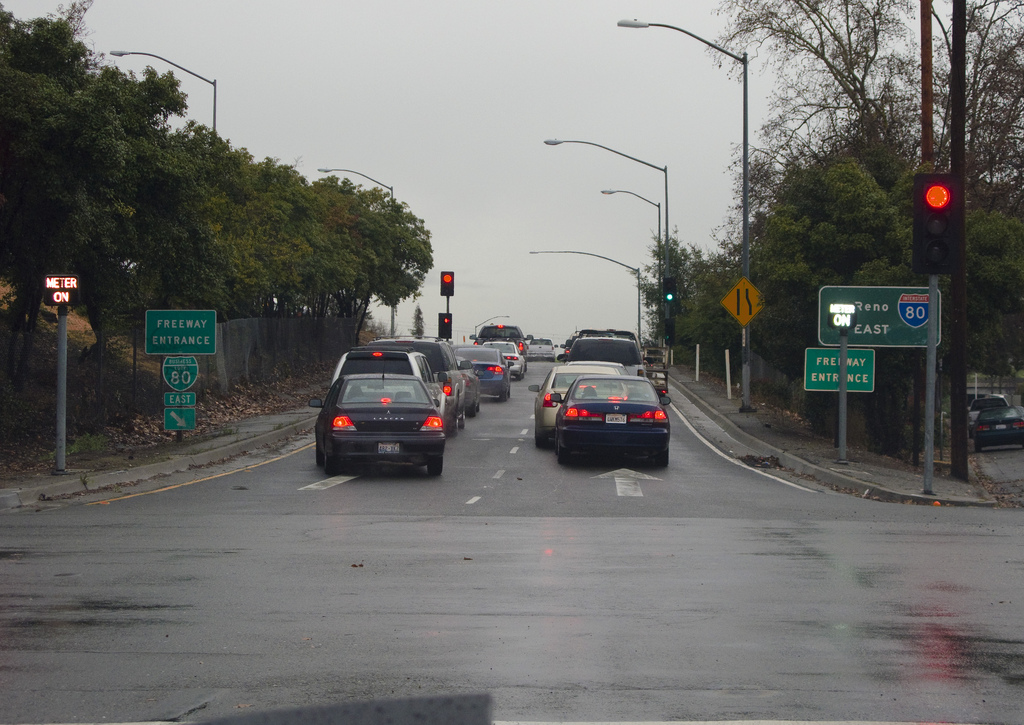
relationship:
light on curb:
[616, 19, 751, 414] [679, 364, 961, 500]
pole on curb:
[915, 27, 950, 324] [679, 364, 961, 500]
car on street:
[313, 357, 451, 475] [353, 450, 697, 630]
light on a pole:
[908, 166, 967, 283] [912, 257, 947, 483]